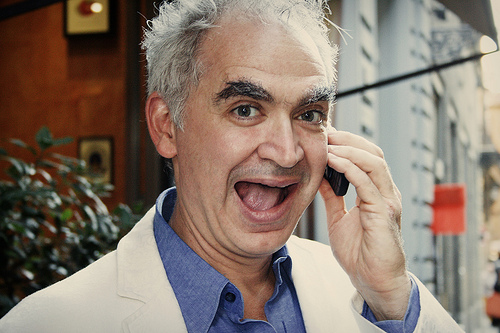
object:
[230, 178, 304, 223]
mouth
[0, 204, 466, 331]
jacket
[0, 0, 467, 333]
gentleman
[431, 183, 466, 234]
banner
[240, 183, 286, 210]
tongue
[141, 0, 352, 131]
hair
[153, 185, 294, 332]
collar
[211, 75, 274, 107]
eyebrow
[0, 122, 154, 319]
plant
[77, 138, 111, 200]
art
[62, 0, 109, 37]
art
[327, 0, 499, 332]
building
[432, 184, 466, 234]
orange paper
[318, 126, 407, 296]
hand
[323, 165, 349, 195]
cellphone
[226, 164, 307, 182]
mustache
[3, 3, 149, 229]
wall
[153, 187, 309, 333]
man's shirt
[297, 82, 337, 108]
eyebrows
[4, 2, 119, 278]
panaling